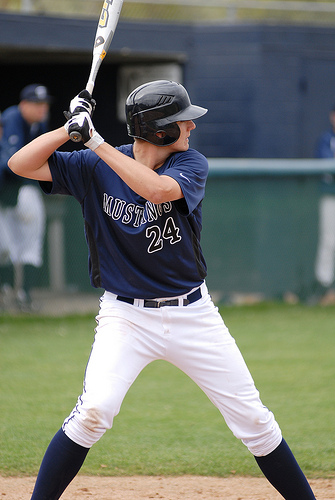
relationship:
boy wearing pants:
[65, 67, 253, 368] [100, 307, 253, 434]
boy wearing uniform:
[65, 67, 253, 368] [74, 155, 269, 480]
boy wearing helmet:
[65, 67, 253, 368] [117, 68, 210, 117]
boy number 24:
[65, 67, 253, 368] [145, 220, 186, 254]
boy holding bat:
[65, 67, 253, 368] [86, 0, 120, 78]